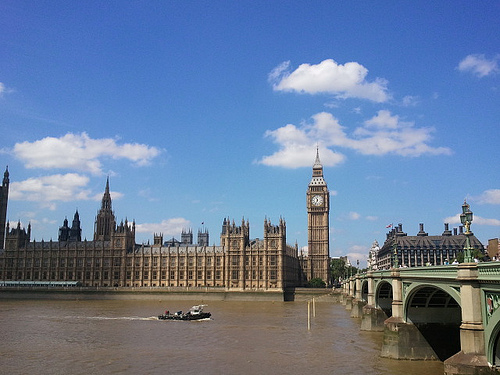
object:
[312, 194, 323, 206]
clock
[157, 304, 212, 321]
boat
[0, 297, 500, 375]
river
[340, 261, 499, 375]
bridge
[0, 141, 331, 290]
building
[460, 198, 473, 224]
lights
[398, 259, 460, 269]
people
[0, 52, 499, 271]
cloud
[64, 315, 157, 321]
waves